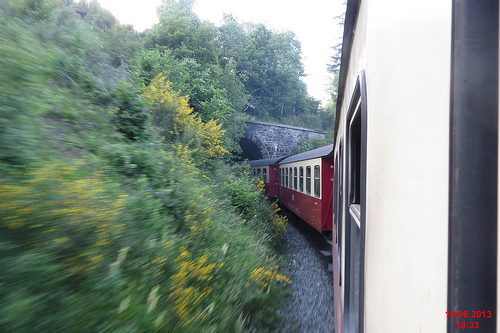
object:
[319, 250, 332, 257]
step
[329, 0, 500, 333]
caboose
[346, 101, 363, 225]
window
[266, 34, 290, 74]
tree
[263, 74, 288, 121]
tree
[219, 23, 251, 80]
tree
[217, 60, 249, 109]
tree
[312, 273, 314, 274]
gravel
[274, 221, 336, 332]
ground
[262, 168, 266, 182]
window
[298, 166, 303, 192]
window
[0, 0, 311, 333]
forestry area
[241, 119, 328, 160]
bridge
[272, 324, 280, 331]
rocks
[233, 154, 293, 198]
railroad car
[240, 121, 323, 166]
grave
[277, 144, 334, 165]
roof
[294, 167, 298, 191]
windows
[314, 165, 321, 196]
window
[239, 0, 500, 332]
train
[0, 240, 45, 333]
bushes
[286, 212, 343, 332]
track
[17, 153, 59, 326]
trees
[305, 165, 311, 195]
window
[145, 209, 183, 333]
shrubbery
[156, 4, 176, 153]
trees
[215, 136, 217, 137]
flowers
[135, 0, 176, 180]
trees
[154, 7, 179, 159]
shrubbery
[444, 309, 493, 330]
stamp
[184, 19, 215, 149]
trees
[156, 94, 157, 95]
flowers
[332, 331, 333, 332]
gravel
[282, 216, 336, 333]
railway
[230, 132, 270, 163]
arch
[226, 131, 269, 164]
tunnel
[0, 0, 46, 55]
bushes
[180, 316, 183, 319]
flowers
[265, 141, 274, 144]
bricks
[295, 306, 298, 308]
gravel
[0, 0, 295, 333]
hillside